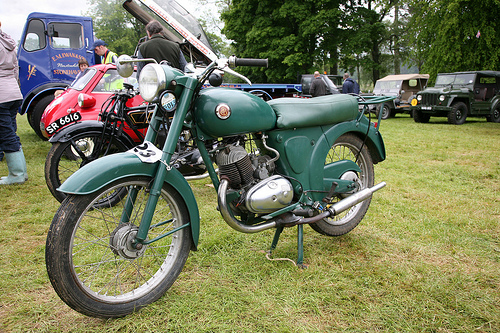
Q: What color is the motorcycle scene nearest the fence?
A: Green.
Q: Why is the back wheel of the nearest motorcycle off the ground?
A: Kickstand.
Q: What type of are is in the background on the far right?
A: Jeep.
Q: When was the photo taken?
A: Daytime.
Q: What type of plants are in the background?
A: Trees.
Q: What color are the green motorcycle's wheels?
A: Black.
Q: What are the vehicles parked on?
A: Grass.